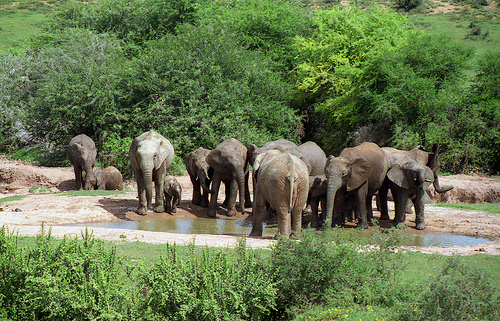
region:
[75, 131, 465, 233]
elephants in shallow water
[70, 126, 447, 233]
dark grey and dry elephants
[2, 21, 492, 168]
green trees behind elephants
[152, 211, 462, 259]
shallow and grey water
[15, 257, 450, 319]
green bushes in front of elephants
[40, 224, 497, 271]
grey dirt around pool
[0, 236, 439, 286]
green grass near pool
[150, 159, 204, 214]
young elephant near water with parents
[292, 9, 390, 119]
light green leaves on tall tree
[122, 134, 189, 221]
grey elephant with child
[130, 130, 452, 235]
elephants in the water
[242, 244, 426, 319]
the green bushes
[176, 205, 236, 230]
the water is brown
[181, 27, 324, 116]
the bushes are green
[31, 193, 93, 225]
the dirt is brown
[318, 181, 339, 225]
the elephants trunk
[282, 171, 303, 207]
the elephants tail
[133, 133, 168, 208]
the elephant is standing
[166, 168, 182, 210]
the small elephant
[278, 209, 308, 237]
back legs on the elephant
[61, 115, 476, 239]
herd of elephants at the watering hole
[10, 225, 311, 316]
bushes near the watering hole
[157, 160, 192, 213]
baby elephant at the watering hole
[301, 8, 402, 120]
lighter green tree in the middle of darker trees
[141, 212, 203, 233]
water in the watering hole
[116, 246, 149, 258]
green grass near the watering hole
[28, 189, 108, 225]
dirt ground at the watering hole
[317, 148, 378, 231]
elephant drinking water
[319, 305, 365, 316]
tiny yellow flowers in the grass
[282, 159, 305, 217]
elephant tail hanging down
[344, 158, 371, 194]
The elephants ear is gray.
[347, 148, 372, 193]
The elephants ear is large.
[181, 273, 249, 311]
The bushes in the forefront are green.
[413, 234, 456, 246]
The water is muddy.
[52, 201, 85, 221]
The dirt is brown in color.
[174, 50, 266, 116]
The tree leaves in the background are green.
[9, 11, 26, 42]
The grass in the background is green.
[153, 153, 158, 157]
The elephants eye is black.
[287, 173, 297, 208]
The elephants tail is long.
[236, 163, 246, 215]
The elephants trunk is long.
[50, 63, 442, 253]
elephants are standing together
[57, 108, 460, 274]
elephants are standing in water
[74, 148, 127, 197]
elephant is sitting down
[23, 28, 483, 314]
elephants are in between trees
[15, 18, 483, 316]
water is in between trees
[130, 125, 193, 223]
baby elephant standing next to adult elephant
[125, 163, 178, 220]
elephant feet are wet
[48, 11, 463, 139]
trees are different shade of green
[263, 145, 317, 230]
elephant has long tail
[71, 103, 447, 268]
elephants facing opposite directions